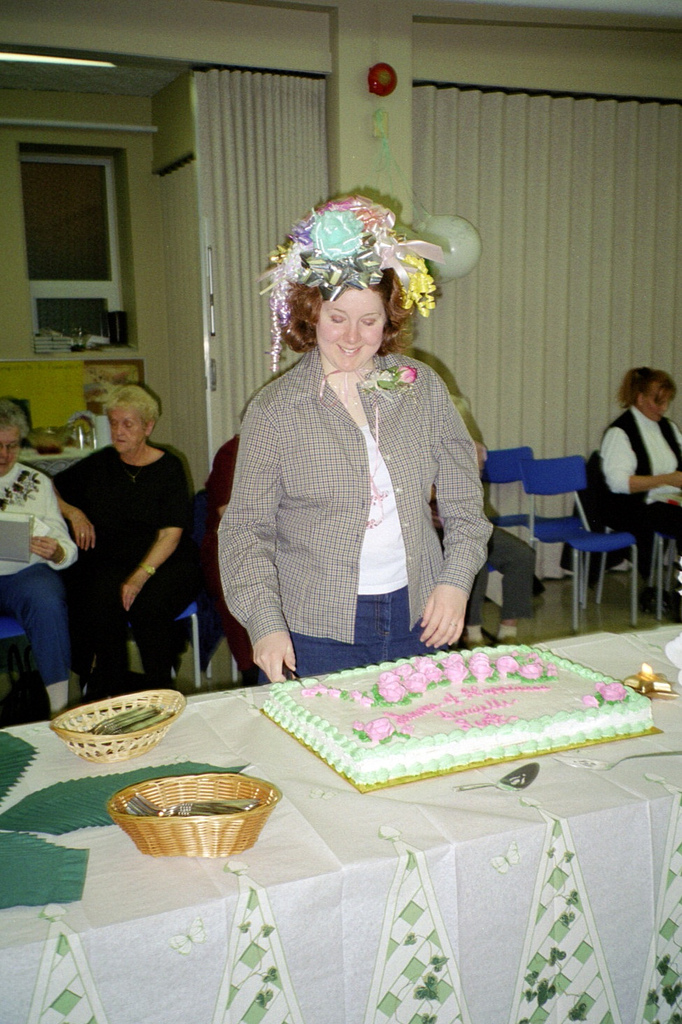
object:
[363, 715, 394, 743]
pinkflowers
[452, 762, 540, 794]
spatulas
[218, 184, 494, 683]
people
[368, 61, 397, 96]
firealarm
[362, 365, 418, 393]
flower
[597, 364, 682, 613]
woman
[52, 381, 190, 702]
woman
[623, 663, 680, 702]
item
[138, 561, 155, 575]
watch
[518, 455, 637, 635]
chair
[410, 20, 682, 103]
wall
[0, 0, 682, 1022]
building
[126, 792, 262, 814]
silverware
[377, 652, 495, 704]
flowers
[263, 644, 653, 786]
cake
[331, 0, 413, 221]
wall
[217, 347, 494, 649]
jacket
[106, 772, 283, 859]
basket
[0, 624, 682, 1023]
table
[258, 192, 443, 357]
hair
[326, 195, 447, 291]
ribbons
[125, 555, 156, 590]
wrist